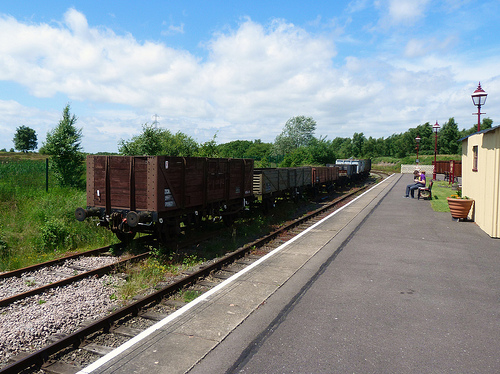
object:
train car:
[86, 154, 254, 212]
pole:
[433, 128, 438, 180]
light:
[432, 120, 441, 133]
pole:
[478, 105, 482, 132]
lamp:
[471, 81, 488, 132]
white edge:
[71, 172, 396, 374]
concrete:
[76, 172, 495, 374]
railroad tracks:
[0, 234, 160, 374]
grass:
[425, 176, 461, 212]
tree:
[39, 101, 87, 187]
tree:
[116, 114, 222, 157]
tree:
[198, 128, 273, 161]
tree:
[265, 115, 335, 167]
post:
[46, 158, 49, 193]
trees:
[368, 121, 434, 157]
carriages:
[74, 154, 372, 241]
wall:
[480, 141, 498, 237]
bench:
[417, 180, 434, 200]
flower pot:
[446, 196, 473, 222]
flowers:
[450, 194, 461, 198]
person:
[404, 170, 426, 199]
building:
[457, 125, 500, 238]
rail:
[0, 170, 389, 374]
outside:
[0, 0, 500, 374]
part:
[42, 265, 97, 288]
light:
[471, 81, 488, 105]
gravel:
[0, 250, 124, 360]